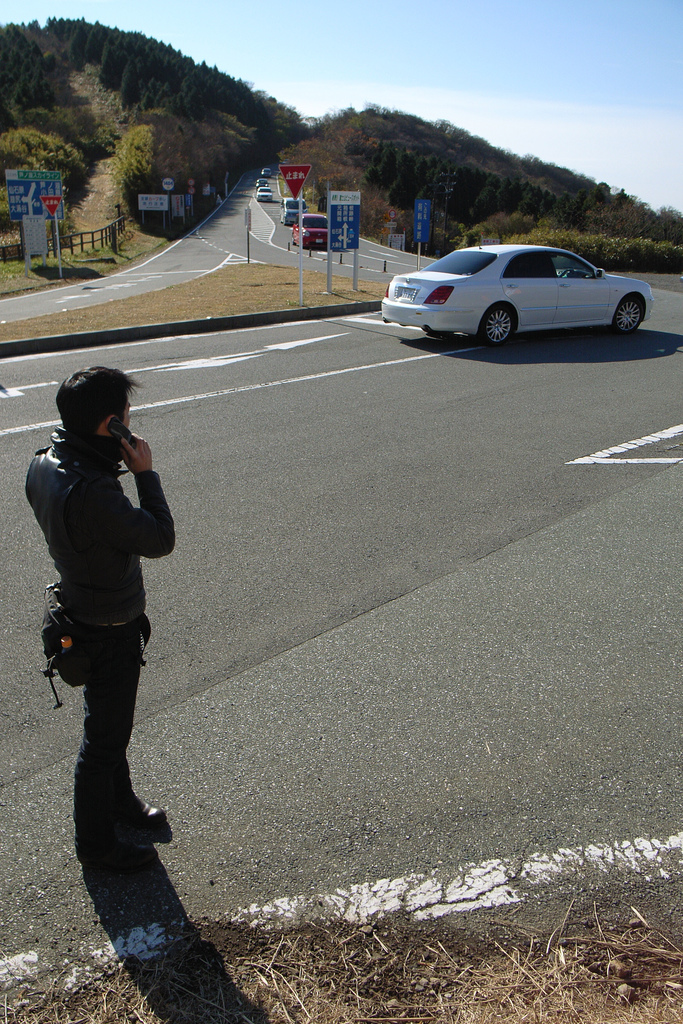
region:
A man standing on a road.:
[20, 361, 175, 879]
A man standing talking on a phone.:
[23, 359, 172, 873]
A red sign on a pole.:
[275, 158, 308, 295]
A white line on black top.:
[1, 854, 673, 975]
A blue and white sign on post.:
[323, 188, 360, 287]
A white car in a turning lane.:
[382, 245, 656, 348]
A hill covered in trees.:
[4, 16, 283, 208]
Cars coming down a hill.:
[247, 162, 334, 250]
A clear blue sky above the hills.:
[293, 9, 681, 119]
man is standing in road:
[20, 353, 203, 886]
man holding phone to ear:
[99, 414, 143, 458]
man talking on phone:
[33, 364, 183, 884]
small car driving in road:
[362, 225, 657, 356]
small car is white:
[370, 232, 661, 355]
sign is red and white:
[273, 159, 315, 195]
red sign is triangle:
[277, 158, 310, 202]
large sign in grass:
[320, 181, 360, 263]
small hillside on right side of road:
[277, 93, 680, 272]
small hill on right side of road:
[4, 10, 304, 304]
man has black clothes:
[19, 357, 213, 869]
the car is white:
[361, 222, 671, 370]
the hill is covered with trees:
[7, 13, 314, 229]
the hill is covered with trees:
[286, 102, 636, 226]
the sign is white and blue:
[315, 177, 368, 301]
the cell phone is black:
[98, 414, 145, 465]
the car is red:
[286, 206, 337, 253]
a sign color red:
[37, 187, 77, 282]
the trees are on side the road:
[100, 121, 156, 190]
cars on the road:
[229, 151, 335, 262]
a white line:
[346, 872, 451, 922]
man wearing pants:
[72, 653, 152, 833]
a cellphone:
[110, 416, 138, 444]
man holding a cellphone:
[116, 437, 152, 473]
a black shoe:
[133, 796, 172, 828]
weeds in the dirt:
[447, 965, 538, 1008]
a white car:
[373, 242, 652, 356]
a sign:
[330, 189, 362, 259]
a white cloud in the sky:
[583, 112, 661, 171]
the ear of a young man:
[80, 405, 150, 467]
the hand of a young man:
[109, 417, 190, 497]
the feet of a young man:
[44, 768, 207, 902]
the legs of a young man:
[46, 592, 202, 882]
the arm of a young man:
[40, 446, 237, 578]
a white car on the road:
[355, 221, 632, 404]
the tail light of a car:
[374, 272, 504, 352]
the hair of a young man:
[37, 335, 150, 500]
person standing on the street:
[17, 354, 195, 877]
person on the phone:
[18, 351, 184, 867]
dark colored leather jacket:
[20, 428, 188, 633]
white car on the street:
[376, 239, 658, 352]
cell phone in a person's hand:
[101, 413, 140, 445]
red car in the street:
[288, 210, 339, 250]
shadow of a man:
[68, 837, 285, 1022]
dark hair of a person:
[58, 359, 140, 439]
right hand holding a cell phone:
[123, 427, 156, 470]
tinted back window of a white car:
[421, 248, 500, 277]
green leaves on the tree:
[396, 159, 421, 173]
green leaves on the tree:
[487, 200, 512, 216]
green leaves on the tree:
[531, 194, 574, 229]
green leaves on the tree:
[409, 156, 447, 195]